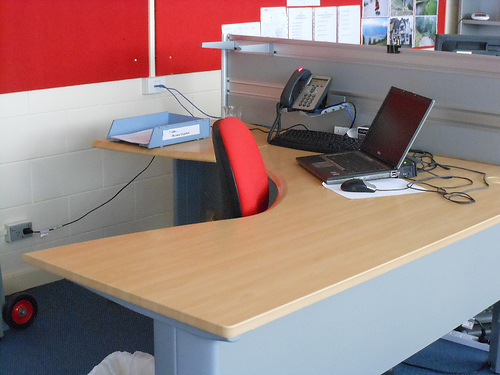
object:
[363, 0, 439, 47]
pictures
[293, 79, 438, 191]
tennis player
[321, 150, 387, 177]
keyboard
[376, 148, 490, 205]
cord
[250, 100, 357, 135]
cord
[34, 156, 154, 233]
cord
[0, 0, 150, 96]
bulletin board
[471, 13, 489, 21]
clock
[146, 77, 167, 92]
outlet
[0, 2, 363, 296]
wall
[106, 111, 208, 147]
planes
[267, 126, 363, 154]
keyboard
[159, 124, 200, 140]
sticker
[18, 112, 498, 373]
desk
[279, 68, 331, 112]
phone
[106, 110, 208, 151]
tray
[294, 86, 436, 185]
computer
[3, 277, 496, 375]
carpet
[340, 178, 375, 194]
mouse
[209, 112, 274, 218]
chair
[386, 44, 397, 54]
clamp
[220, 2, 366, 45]
bulletin board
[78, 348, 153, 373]
bag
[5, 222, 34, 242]
outlet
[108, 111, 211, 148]
inbox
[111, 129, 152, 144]
paper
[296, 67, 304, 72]
light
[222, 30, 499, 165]
divider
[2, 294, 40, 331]
tire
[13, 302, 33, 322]
inner tire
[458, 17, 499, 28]
shelf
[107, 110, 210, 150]
shelf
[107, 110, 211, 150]
holder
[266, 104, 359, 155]
stand